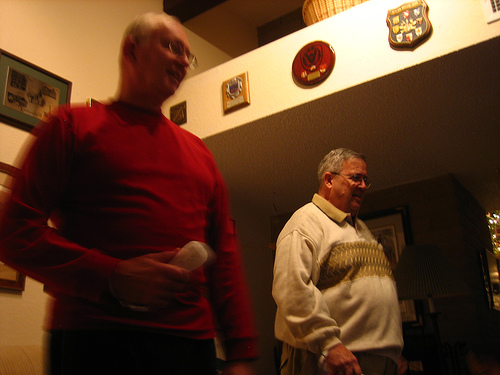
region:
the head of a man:
[309, 142, 376, 215]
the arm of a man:
[268, 225, 349, 351]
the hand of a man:
[316, 338, 368, 373]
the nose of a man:
[356, 174, 369, 192]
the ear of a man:
[321, 167, 338, 190]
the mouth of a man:
[351, 190, 366, 204]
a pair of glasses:
[324, 165, 379, 188]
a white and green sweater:
[268, 198, 410, 355]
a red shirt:
[1, 89, 269, 361]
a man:
[261, 132, 408, 372]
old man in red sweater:
[13, 14, 239, 356]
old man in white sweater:
[287, 145, 418, 374]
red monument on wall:
[273, 37, 349, 89]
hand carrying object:
[112, 235, 232, 310]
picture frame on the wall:
[4, 41, 100, 147]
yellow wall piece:
[205, 65, 277, 118]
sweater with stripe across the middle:
[296, 201, 405, 368]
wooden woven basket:
[286, 2, 362, 38]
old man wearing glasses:
[107, 12, 207, 104]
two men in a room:
[22, 12, 405, 372]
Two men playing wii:
[62, 20, 419, 325]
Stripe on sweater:
[315, 226, 397, 281]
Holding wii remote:
[157, 230, 232, 301]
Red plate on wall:
[290, 39, 338, 88]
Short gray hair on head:
[313, 137, 382, 211]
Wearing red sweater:
[31, 96, 256, 327]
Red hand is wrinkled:
[313, 335, 363, 373]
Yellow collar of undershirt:
[312, 193, 349, 225]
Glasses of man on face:
[158, 35, 206, 69]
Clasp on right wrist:
[309, 335, 344, 362]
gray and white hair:
[307, 142, 370, 196]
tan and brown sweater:
[275, 213, 435, 354]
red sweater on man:
[41, 98, 243, 317]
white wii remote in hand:
[159, 234, 230, 282]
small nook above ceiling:
[206, 0, 291, 42]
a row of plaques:
[203, 17, 417, 59]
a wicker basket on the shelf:
[295, 6, 345, 27]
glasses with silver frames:
[142, 29, 218, 73]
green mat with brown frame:
[4, 43, 80, 121]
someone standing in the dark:
[389, 178, 489, 355]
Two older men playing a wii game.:
[26, 7, 438, 367]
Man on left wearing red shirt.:
[11, 11, 263, 372]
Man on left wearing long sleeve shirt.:
[14, 75, 254, 362]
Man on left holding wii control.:
[12, 15, 252, 350]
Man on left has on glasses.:
[92, 6, 202, 121]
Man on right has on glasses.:
[260, 125, 425, 243]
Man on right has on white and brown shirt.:
[261, 135, 416, 370]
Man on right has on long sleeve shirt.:
[260, 175, 410, 360]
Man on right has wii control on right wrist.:
[303, 322, 360, 372]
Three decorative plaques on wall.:
[212, 0, 443, 115]